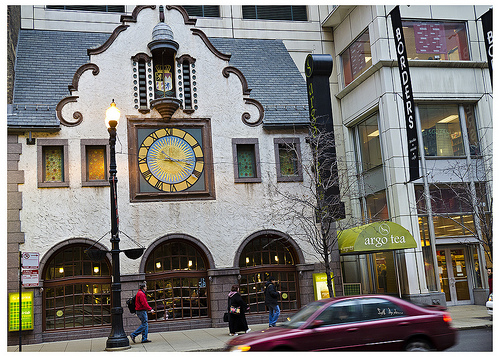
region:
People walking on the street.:
[121, 265, 301, 350]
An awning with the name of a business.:
[332, 215, 414, 295]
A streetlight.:
[90, 90, 135, 345]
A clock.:
[121, 110, 216, 205]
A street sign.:
[10, 245, 45, 350]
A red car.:
[220, 285, 465, 350]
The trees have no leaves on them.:
[265, 122, 495, 307]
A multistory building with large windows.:
[330, 0, 490, 295]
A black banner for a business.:
[377, 6, 442, 187]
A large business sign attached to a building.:
[293, 47, 348, 232]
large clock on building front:
[119, 105, 237, 235]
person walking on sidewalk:
[122, 274, 187, 354]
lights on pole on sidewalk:
[97, 90, 148, 350]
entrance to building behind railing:
[124, 224, 249, 335]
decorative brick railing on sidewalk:
[152, 258, 289, 345]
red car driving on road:
[210, 286, 481, 351]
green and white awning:
[337, 216, 452, 291]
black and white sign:
[387, 9, 431, 191]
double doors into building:
[419, 230, 499, 321]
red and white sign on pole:
[14, 261, 40, 355]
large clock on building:
[115, 102, 219, 250]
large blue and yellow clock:
[111, 109, 237, 220]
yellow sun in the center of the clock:
[144, 139, 189, 178]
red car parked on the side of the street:
[213, 280, 470, 348]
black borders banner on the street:
[382, 10, 444, 190]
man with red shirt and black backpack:
[128, 277, 164, 354]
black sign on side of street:
[286, 41, 353, 241]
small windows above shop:
[27, 141, 120, 188]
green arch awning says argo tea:
[319, 205, 426, 282]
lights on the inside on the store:
[37, 243, 296, 309]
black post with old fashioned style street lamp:
[91, 92, 146, 347]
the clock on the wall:
[122, 112, 224, 200]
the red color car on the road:
[245, 298, 461, 349]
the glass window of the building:
[410, 91, 497, 158]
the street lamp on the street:
[89, 91, 134, 349]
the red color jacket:
[132, 285, 152, 313]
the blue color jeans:
[130, 310, 155, 347]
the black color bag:
[120, 293, 140, 318]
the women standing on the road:
[222, 282, 250, 339]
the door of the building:
[435, 235, 477, 306]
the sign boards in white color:
[15, 247, 45, 350]